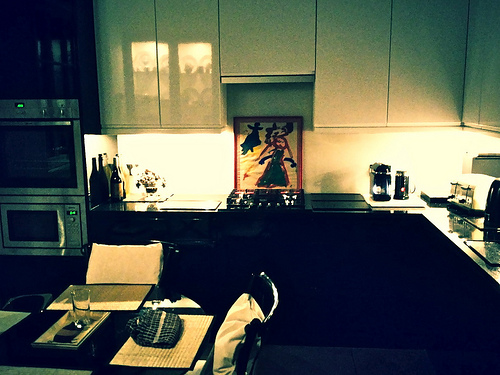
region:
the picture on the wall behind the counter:
[232, 111, 302, 190]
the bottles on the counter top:
[91, 148, 124, 206]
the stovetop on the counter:
[226, 188, 302, 208]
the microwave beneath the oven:
[1, 197, 84, 257]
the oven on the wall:
[1, 98, 84, 198]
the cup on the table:
[68, 289, 93, 323]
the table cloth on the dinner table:
[116, 303, 209, 374]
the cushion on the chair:
[211, 286, 269, 373]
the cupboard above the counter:
[97, 6, 226, 133]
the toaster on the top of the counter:
[447, 178, 487, 216]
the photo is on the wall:
[201, 77, 416, 304]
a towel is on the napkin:
[121, 298, 166, 355]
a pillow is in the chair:
[231, 272, 284, 372]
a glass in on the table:
[53, 278, 109, 355]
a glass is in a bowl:
[46, 272, 128, 365]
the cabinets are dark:
[307, 221, 473, 363]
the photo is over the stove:
[214, 109, 396, 341]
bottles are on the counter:
[87, 145, 167, 252]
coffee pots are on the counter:
[350, 155, 441, 241]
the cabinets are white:
[112, 29, 274, 124]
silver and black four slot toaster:
[443, 165, 498, 237]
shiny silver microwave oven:
[0, 198, 87, 255]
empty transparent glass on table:
[66, 285, 93, 330]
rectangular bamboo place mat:
[109, 301, 214, 371]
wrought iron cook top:
[222, 184, 302, 212]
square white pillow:
[75, 238, 165, 291]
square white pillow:
[207, 284, 270, 374]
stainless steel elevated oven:
[2, 93, 97, 200]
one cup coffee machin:
[355, 160, 390, 203]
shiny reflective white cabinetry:
[92, 0, 498, 135]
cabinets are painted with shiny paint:
[102, 11, 160, 121]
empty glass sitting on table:
[67, 286, 100, 326]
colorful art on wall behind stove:
[232, 112, 310, 192]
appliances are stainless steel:
[0, 94, 95, 254]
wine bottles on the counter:
[107, 155, 124, 203]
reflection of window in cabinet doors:
[115, 31, 230, 131]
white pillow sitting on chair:
[216, 291, 265, 371]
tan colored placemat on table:
[47, 283, 153, 309]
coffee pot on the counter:
[364, 158, 399, 199]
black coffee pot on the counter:
[360, 161, 398, 205]